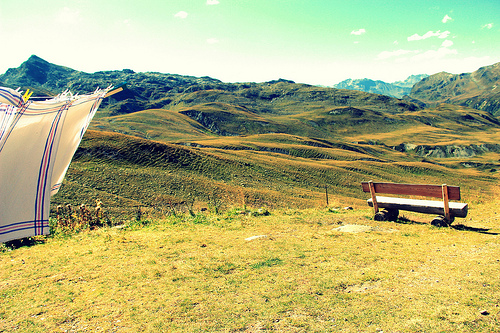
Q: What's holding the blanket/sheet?
A: Clothesline.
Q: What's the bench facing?
A: Mountains.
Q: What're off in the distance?
A: Mountains.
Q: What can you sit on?
A: Bench.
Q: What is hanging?
A: Blanket.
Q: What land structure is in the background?
A: Mountains.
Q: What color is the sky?
A: Blue.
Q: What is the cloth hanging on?
A: Line.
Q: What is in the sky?
A: Clouds.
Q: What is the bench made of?
A: Wood.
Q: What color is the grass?
A: Green.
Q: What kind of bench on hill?
A: Wooden.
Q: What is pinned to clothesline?
A: Towels.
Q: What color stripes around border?
A: Red and blue.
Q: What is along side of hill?
A: Fencing.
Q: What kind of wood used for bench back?
A: Plank.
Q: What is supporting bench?
A: Two short logs.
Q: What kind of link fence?
A: Small chain.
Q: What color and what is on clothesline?
A: Red, white and blue tablecloth.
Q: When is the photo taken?
A: Daytime.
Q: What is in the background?
A: Mountains.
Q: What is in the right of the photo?
A: A bench.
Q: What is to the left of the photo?
A: A blanket.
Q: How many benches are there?
A: One.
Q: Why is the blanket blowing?
A: It is windy.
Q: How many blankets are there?
A: One.